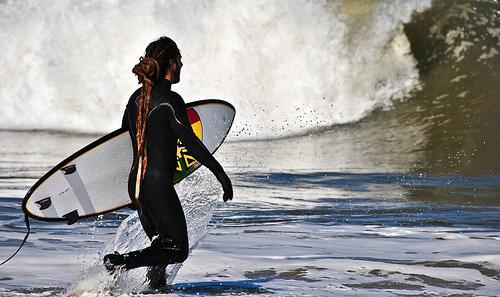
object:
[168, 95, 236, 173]
arm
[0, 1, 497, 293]
water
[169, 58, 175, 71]
ear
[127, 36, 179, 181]
hair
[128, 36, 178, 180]
dreaded hair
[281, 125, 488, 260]
water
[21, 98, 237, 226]
surf board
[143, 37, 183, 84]
head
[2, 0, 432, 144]
big wave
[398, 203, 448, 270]
ground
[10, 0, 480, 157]
water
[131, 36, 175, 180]
dreadlocks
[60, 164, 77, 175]
fin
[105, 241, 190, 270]
leg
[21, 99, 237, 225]
surfboard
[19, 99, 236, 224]
board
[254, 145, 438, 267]
water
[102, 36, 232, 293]
surfer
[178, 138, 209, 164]
elbow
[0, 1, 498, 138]
wave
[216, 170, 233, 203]
hand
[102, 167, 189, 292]
legs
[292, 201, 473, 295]
water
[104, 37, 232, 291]
man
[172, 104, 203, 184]
design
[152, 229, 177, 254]
foot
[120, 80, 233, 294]
wet suit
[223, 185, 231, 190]
part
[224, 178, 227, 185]
part